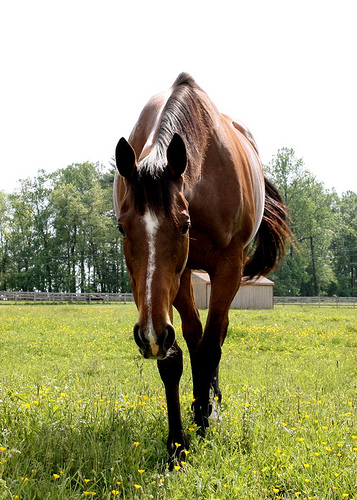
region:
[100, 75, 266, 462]
brown horse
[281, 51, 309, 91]
white clouds in blue sky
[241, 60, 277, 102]
white clouds in blue sky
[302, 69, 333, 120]
white clouds in blue sky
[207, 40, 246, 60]
white clouds in blue sky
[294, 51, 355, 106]
white clouds in blue sky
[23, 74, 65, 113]
white clouds in blue sky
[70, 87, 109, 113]
white clouds in blue sky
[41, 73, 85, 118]
white clouds in blue sky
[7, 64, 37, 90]
white clouds in blue sky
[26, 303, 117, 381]
field covered in grass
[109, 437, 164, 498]
small yellow flowers in grass field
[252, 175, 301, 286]
long brown hair on horse tail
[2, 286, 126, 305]
wooden fencing on edge of field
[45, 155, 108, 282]
trees covered in green leaves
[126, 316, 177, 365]
large nostrils on horse nose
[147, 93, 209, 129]
brown hair on back of horse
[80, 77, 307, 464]
horse walking in field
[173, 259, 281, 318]
brown building behind horse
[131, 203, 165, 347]
white stripe on head of horse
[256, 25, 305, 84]
white clouds in blue sky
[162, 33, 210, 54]
white clouds in blue sky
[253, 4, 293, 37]
white clouds in blue sky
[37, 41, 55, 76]
white clouds in blue sky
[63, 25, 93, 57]
white clouds in blue sky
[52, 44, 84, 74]
white clouds in blue sky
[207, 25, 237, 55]
white clouds in blue sky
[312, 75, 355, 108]
white clouds in blue sky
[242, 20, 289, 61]
white clouds in blue sky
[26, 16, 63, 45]
white clouds in blue sky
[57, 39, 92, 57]
white clouds in blue sky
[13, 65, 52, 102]
white clouds in blue sky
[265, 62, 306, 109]
white clouds in blue sky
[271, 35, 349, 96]
white clouds in blue sky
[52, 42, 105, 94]
white clouds in blue sky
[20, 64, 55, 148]
white clouds in blue sky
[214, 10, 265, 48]
white clouds in blue sky